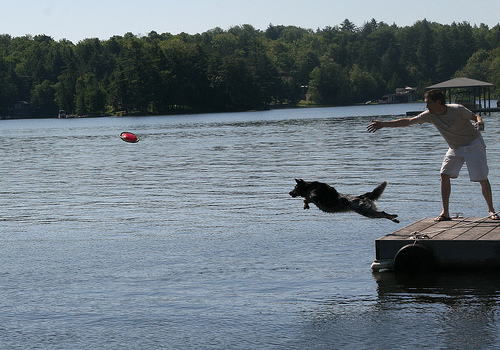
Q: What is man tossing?
A: Frisbee.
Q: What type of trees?
A: Pine.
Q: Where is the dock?
A: In water.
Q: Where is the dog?
A: In air.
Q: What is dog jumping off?
A: Pier.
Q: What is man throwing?
A: Frisbee.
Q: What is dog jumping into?
A: Water.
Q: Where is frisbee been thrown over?
A: Water.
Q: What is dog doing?
A: Jumping.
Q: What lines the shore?
A: Trees.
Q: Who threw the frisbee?
A: The man.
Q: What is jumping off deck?
A: Black dog.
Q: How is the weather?
A: Warm and clear.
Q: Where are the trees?
A: Far distance.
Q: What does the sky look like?
A: Blue and clear.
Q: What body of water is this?
A: Lake.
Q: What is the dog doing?
A: Chasing a frisbee.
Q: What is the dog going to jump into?
A: Water.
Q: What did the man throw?
A: A frisbee.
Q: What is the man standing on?
A: A dock.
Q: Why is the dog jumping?
A: To catch a frisbee.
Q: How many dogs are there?
A: One.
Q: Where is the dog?
A: In the air.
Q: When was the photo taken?
A: During the day.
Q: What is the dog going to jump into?
A: The water.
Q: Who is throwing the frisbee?
A: A man.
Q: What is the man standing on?
A: A pier.